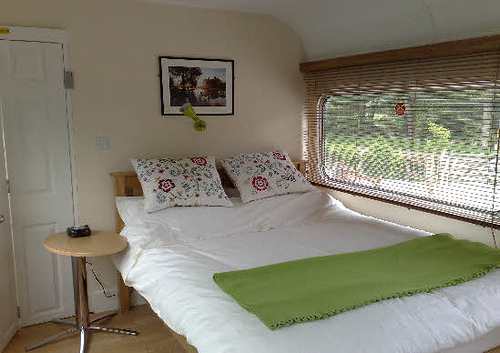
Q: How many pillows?
A: Two.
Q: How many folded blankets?
A: One.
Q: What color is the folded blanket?
A: Green.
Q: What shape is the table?
A: Round.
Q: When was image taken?
A: Daytime.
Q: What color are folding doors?
A: White.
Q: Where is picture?
A: Over bed.